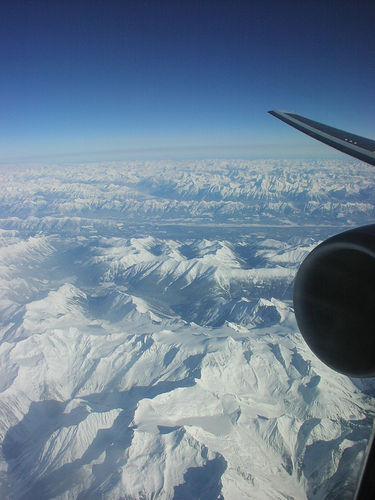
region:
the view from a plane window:
[8, 52, 371, 490]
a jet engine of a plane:
[291, 205, 374, 404]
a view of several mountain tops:
[4, 152, 341, 485]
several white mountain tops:
[29, 162, 311, 499]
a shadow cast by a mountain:
[11, 385, 178, 484]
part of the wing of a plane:
[256, 92, 372, 186]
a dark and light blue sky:
[5, 18, 357, 177]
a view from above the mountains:
[20, 114, 373, 435]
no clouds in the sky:
[31, 14, 373, 176]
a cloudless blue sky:
[10, 11, 350, 214]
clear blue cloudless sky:
[16, 9, 204, 129]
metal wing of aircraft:
[269, 106, 373, 173]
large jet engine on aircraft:
[279, 204, 373, 381]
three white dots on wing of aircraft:
[333, 132, 360, 149]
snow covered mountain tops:
[6, 157, 351, 221]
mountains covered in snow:
[225, 440, 266, 465]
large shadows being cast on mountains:
[15, 391, 87, 452]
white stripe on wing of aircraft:
[273, 106, 315, 137]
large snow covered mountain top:
[99, 286, 166, 331]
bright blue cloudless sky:
[3, 5, 374, 105]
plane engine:
[268, 215, 373, 410]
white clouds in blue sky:
[97, 115, 125, 146]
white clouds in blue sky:
[84, 110, 127, 144]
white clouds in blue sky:
[64, 39, 115, 81]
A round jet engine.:
[261, 225, 372, 385]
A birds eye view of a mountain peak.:
[88, 380, 251, 483]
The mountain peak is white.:
[109, 398, 221, 471]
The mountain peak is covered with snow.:
[72, 377, 277, 491]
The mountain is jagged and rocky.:
[41, 286, 277, 497]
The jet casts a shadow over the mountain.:
[17, 361, 223, 498]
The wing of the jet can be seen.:
[269, 97, 371, 155]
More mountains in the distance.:
[30, 153, 373, 236]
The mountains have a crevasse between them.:
[52, 187, 300, 253]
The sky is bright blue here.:
[75, 22, 208, 88]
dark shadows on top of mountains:
[2, 373, 192, 476]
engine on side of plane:
[283, 219, 373, 380]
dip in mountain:
[129, 258, 195, 301]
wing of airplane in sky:
[264, 98, 371, 177]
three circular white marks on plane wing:
[339, 131, 364, 146]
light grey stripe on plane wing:
[268, 104, 373, 165]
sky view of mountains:
[5, 159, 371, 497]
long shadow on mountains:
[141, 178, 372, 209]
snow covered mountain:
[2, 316, 197, 408]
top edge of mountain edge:
[46, 325, 89, 340]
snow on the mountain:
[192, 420, 280, 498]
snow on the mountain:
[258, 327, 303, 382]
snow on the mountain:
[102, 418, 181, 487]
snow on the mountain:
[70, 329, 140, 377]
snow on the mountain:
[148, 242, 188, 286]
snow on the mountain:
[32, 275, 81, 325]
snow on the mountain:
[251, 159, 297, 201]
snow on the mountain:
[185, 165, 209, 200]